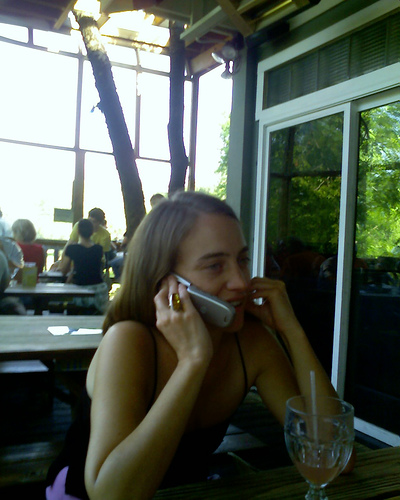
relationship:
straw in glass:
[310, 371, 320, 469] [282, 393, 354, 499]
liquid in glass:
[294, 454, 344, 486] [282, 393, 354, 499]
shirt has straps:
[64, 317, 248, 498] [147, 328, 160, 398]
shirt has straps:
[64, 317, 248, 498] [232, 335, 250, 391]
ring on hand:
[168, 292, 179, 308] [154, 272, 213, 361]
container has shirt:
[20, 261, 37, 287] [12, 241, 45, 276]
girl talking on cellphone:
[70, 188, 334, 490] [127, 258, 252, 350]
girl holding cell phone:
[64, 188, 345, 500] [149, 266, 236, 336]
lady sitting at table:
[77, 192, 350, 489] [40, 371, 395, 498]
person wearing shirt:
[8, 218, 46, 275] [14, 242, 46, 270]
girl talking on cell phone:
[64, 188, 345, 500] [169, 271, 236, 328]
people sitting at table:
[0, 205, 120, 295] [4, 272, 108, 297]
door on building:
[265, 89, 394, 442] [237, 0, 396, 274]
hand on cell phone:
[154, 272, 213, 361] [169, 271, 236, 328]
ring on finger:
[168, 292, 183, 313] [165, 272, 177, 297]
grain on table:
[349, 474, 397, 494] [234, 449, 399, 495]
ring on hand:
[168, 292, 183, 313] [154, 272, 213, 361]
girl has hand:
[70, 188, 334, 490] [154, 272, 213, 361]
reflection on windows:
[263, 100, 393, 305] [275, 125, 336, 291]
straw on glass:
[306, 366, 319, 462] [238, 355, 379, 476]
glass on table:
[276, 388, 361, 496] [196, 441, 399, 498]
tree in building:
[71, 20, 209, 243] [6, 2, 394, 498]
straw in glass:
[310, 371, 320, 469] [265, 363, 365, 495]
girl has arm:
[64, 188, 345, 500] [85, 283, 223, 498]